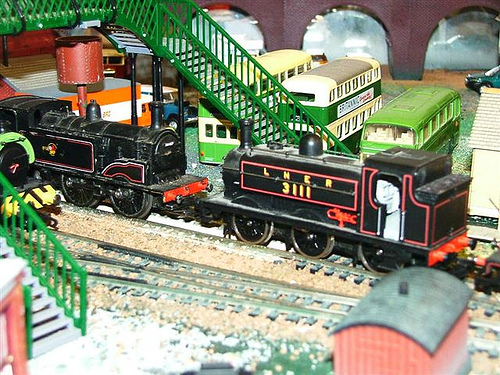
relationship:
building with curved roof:
[311, 245, 468, 373] [330, 248, 471, 348]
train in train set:
[0, 95, 500, 295] [1, 69, 471, 267]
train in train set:
[0, 95, 472, 272] [2, 1, 499, 373]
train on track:
[0, 95, 472, 272] [55, 187, 499, 319]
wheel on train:
[353, 238, 395, 272] [2, 76, 212, 220]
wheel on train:
[288, 215, 333, 260] [0, 95, 472, 272]